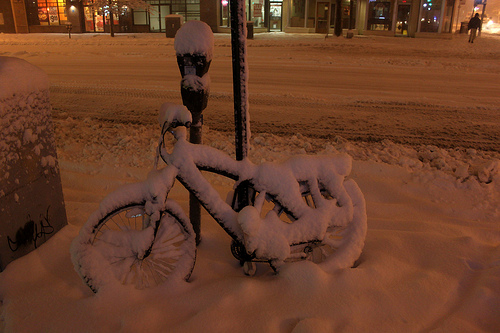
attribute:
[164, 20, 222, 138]
park meter — metal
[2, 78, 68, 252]
box — large, grey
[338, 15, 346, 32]
pole — tall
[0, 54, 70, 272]
block — concrete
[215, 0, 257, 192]
post — black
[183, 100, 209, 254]
pole — gray, metal